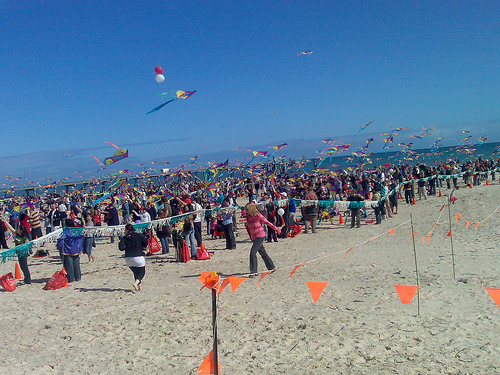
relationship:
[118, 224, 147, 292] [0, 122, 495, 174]
woman watching kites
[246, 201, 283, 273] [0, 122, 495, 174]
woman watching kites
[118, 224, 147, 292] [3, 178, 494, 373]
woman on beach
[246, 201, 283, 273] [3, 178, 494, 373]
woman on beach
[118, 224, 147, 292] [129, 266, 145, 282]
woman wearing pants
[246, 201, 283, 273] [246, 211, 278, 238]
woman wearing shirt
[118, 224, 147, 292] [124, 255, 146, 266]
woman wearing under-shirt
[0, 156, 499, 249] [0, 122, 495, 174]
people flying kites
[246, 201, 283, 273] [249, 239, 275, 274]
woman wearing pants